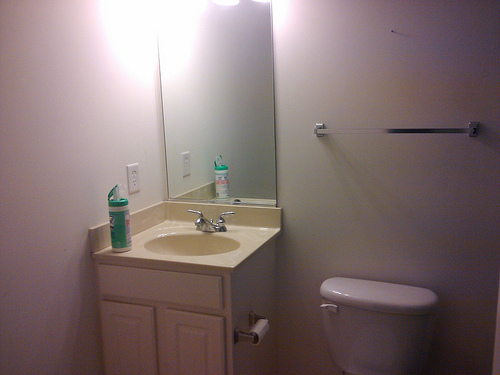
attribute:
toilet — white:
[311, 270, 459, 373]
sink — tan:
[86, 187, 286, 290]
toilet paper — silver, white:
[247, 317, 269, 336]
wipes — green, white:
[101, 182, 140, 259]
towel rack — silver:
[308, 117, 481, 146]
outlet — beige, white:
[125, 162, 147, 196]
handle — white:
[318, 300, 340, 315]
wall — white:
[282, 5, 485, 130]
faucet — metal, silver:
[195, 217, 211, 227]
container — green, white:
[107, 211, 132, 252]